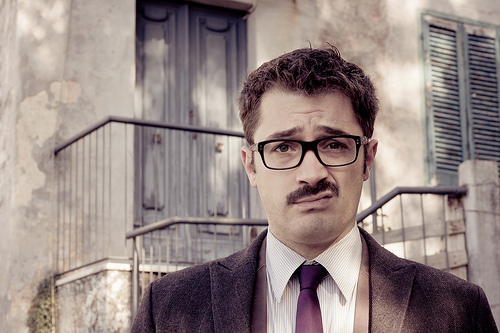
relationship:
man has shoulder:
[134, 49, 497, 328] [361, 228, 495, 327]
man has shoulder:
[134, 49, 497, 328] [130, 229, 266, 327]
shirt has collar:
[264, 226, 362, 331] [263, 229, 362, 303]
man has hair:
[134, 49, 497, 328] [238, 48, 378, 144]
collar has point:
[263, 229, 362, 303] [266, 228, 308, 303]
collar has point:
[263, 229, 362, 303] [310, 223, 364, 303]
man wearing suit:
[134, 49, 497, 328] [249, 229, 370, 329]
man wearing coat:
[134, 49, 497, 328] [131, 226, 497, 329]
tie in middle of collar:
[289, 263, 329, 330] [263, 229, 362, 303]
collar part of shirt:
[263, 229, 362, 303] [264, 226, 362, 331]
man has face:
[134, 49, 497, 328] [256, 120, 365, 244]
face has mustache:
[256, 120, 365, 244] [287, 181, 338, 205]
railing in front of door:
[54, 116, 269, 281] [133, 4, 250, 264]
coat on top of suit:
[131, 226, 497, 329] [249, 229, 370, 329]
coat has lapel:
[131, 226, 497, 329] [208, 259, 255, 327]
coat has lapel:
[131, 226, 497, 329] [371, 262, 419, 330]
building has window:
[8, 5, 495, 327] [416, 9, 496, 183]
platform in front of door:
[55, 260, 190, 330] [133, 4, 250, 264]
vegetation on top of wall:
[27, 275, 56, 330] [5, 4, 133, 330]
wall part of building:
[5, 4, 133, 330] [8, 5, 495, 327]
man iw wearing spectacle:
[134, 49, 497, 328] [246, 135, 368, 170]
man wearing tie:
[134, 49, 497, 328] [289, 263, 329, 330]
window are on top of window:
[416, 9, 496, 183] [416, 4, 496, 183]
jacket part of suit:
[253, 228, 369, 328] [249, 229, 370, 329]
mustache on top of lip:
[287, 181, 338, 205] [295, 190, 333, 203]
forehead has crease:
[255, 87, 355, 126] [287, 107, 323, 116]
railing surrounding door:
[54, 116, 269, 281] [133, 4, 250, 264]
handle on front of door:
[151, 131, 163, 145] [133, 4, 250, 264]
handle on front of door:
[215, 142, 227, 154] [133, 4, 250, 264]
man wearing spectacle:
[134, 49, 497, 328] [246, 135, 368, 170]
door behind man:
[133, 4, 250, 264] [134, 49, 497, 328]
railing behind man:
[54, 116, 269, 281] [134, 49, 497, 328]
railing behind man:
[358, 184, 468, 282] [134, 49, 497, 328]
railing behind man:
[125, 214, 266, 317] [134, 49, 497, 328]